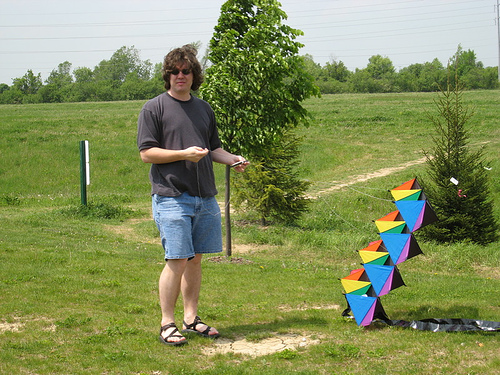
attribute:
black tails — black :
[381, 314, 498, 338]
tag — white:
[436, 162, 477, 202]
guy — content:
[131, 52, 286, 353]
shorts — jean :
[151, 192, 223, 258]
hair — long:
[161, 52, 205, 83]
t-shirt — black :
[136, 39, 236, 344]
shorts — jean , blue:
[146, 190, 223, 257]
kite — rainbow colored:
[345, 198, 420, 282]